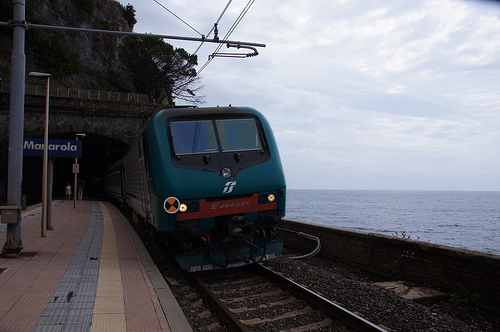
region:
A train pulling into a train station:
[95, 100, 293, 280]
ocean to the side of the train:
[328, 195, 485, 221]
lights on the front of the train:
[168, 188, 276, 208]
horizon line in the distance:
[301, 178, 489, 201]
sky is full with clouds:
[316, 58, 455, 148]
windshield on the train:
[155, 114, 264, 156]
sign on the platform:
[18, 138, 80, 159]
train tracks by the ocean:
[192, 282, 347, 329]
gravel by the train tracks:
[316, 270, 376, 310]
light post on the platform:
[26, 58, 52, 238]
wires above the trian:
[171, 8, 216, 130]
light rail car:
[102, 81, 282, 252]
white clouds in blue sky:
[318, 12, 359, 57]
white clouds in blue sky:
[392, 92, 467, 156]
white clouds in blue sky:
[345, 43, 425, 87]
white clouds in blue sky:
[387, 5, 428, 77]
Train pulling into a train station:
[91, 102, 288, 282]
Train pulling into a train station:
[100, 100, 290, 277]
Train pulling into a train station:
[96, 100, 288, 281]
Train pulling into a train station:
[95, 100, 291, 277]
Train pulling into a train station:
[97, 96, 288, 278]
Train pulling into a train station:
[96, 96, 286, 283]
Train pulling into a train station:
[90, 95, 300, 282]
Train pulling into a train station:
[90, 100, 302, 288]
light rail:
[108, 71, 278, 261]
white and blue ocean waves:
[435, 123, 467, 161]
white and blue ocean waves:
[307, 102, 349, 159]